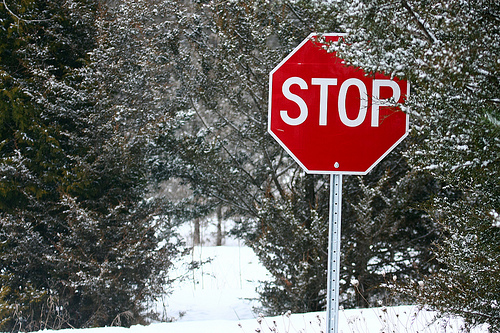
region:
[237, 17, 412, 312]
this is a sign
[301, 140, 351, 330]
this is a sign post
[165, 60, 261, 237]
this is a branch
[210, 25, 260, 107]
this is a branch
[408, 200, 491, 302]
this is a branch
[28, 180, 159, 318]
this is a branch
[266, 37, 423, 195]
a red stop sign on a pole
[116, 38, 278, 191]
trees covered in snow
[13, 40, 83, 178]
the green of a pine tree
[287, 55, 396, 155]
the word stop in white letters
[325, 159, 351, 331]
metal pole for the stop sign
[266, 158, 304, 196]
the branches of a tree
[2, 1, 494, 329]
a winter scene with snow and trees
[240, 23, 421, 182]
stop sign behind the tree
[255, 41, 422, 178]
stop sign behind the tree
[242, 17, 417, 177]
stop sign behind the tree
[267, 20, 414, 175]
stop sign behind the tree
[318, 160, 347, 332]
stop sign attached to a pole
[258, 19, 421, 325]
stop sign attached to a pole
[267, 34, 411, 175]
stop sign is red and white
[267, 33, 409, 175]
stop sign is on a post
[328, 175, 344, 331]
silver post is holding a stop sign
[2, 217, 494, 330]
snow is covering the ground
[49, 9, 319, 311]
tree is covered in white snow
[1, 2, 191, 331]
tree is covered in white snow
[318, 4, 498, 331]
tree is covered in white snow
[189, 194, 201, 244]
tree has a light brown trunk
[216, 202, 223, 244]
tree has a light brown trunk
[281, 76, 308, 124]
stop sign has the white letter s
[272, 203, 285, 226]
picture of a steam train on tracks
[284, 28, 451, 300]
a sign on a pole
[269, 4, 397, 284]
a sign on a metal pole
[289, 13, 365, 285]
a pole with a sign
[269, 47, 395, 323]
a metal pole with sign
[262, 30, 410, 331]
red and white octagonal stop sign on a metal pole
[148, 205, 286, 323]
snowy pathway between some trees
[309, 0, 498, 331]
tree with snow on its leaves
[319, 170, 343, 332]
metal post sticking out of some snow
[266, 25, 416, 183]
A red and white stop sign.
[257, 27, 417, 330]
A stop sign in the snow.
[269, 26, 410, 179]
A red and white street sign.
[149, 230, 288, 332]
A snow covered hill.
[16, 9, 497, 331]
Trees behind the stop sign.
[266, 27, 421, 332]
The sign is in the snow.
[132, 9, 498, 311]
snow on the tree branches.